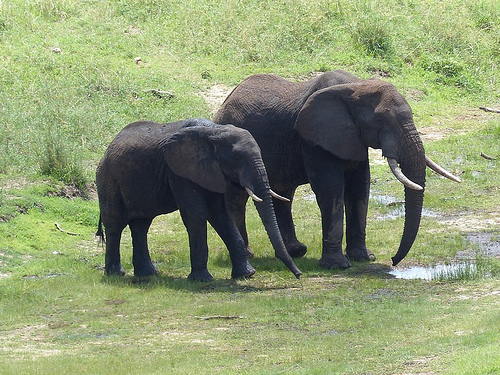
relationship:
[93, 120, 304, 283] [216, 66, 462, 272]
baby elephant next to elephant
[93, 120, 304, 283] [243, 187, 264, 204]
baby elephant has tusk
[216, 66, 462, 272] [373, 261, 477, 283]
elephant drinking puddle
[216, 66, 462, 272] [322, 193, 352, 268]
elephant has dried mud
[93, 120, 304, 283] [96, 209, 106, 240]
baby elephant has tail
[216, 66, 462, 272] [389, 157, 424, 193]
elephant has tusk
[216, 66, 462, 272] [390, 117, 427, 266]
elephant has trunk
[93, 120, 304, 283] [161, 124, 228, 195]
baby elephant has ear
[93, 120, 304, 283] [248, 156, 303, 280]
baby elephant has trunk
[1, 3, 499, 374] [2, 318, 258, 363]
grass has dirt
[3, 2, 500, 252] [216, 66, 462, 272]
hill behind elephant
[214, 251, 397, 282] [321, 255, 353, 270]
shadow under foot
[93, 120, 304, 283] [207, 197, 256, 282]
baby elephant has front leg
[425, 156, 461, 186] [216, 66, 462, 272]
tusk on elephant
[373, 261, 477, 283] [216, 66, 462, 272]
puddle before elephant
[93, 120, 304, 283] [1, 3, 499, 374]
baby elephant in grass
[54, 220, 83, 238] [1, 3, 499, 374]
branch in grass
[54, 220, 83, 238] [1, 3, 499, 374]
branch on grass